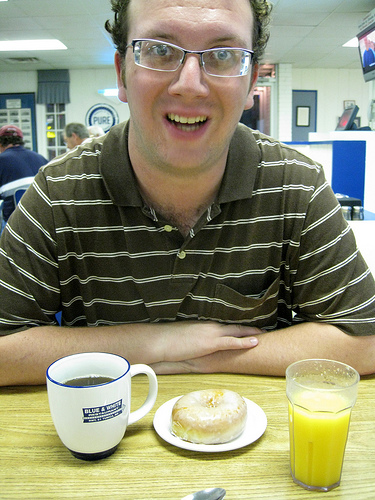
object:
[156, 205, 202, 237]
chest hair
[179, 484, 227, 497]
silver spoon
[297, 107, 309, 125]
sign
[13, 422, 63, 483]
brown table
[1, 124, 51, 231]
man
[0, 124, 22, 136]
hat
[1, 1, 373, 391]
man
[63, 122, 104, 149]
person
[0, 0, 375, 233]
background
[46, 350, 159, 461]
mug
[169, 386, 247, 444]
donut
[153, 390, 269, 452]
plate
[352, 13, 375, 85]
television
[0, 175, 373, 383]
arms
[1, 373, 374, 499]
table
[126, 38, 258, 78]
eyeglasses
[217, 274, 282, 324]
pocket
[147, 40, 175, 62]
eye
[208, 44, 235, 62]
eye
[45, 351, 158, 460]
cup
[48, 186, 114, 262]
stripes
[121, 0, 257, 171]
face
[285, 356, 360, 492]
glass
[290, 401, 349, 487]
juice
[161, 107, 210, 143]
mouth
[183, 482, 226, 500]
tip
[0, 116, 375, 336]
polo shirt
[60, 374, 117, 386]
coffee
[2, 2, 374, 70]
ceiling